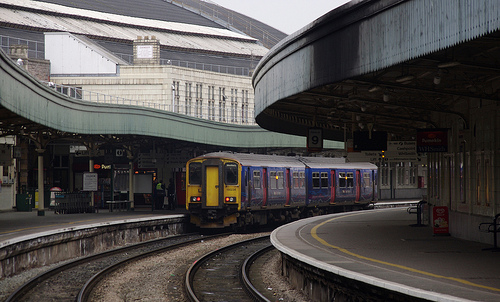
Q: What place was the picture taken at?
A: It was taken at the station.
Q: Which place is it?
A: It is a station.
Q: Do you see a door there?
A: Yes, there is a door.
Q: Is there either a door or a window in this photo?
A: Yes, there is a door.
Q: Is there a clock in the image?
A: No, there are no clocks.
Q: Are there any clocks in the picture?
A: No, there are no clocks.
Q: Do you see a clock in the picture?
A: No, there are no clocks.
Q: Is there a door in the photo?
A: Yes, there is a door.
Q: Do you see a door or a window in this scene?
A: Yes, there is a door.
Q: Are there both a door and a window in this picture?
A: Yes, there are both a door and a window.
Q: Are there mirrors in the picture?
A: No, there are no mirrors.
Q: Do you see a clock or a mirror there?
A: No, there are no mirrors or clocks.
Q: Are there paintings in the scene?
A: No, there are no paintings.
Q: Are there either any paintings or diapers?
A: No, there are no paintings or diapers.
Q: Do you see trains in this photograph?
A: Yes, there is a train.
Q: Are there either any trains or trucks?
A: Yes, there is a train.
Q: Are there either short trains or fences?
A: Yes, there is a short train.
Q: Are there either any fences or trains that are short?
A: Yes, the train is short.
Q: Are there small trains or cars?
A: Yes, there is a small train.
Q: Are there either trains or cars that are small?
A: Yes, the train is small.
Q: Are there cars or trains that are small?
A: Yes, the train is small.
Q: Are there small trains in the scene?
A: Yes, there is a small train.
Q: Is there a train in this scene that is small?
A: Yes, there is a train that is small.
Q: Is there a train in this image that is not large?
A: Yes, there is a small train.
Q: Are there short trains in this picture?
A: Yes, there is a short train.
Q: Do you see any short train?
A: Yes, there is a short train.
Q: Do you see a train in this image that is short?
A: Yes, there is a train that is short.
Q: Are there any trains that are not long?
A: Yes, there is a short train.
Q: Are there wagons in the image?
A: No, there are no wagons.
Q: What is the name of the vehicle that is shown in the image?
A: The vehicle is a train.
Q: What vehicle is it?
A: The vehicle is a train.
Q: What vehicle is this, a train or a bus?
A: That is a train.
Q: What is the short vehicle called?
A: The vehicle is a train.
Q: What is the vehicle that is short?
A: The vehicle is a train.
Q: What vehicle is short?
A: The vehicle is a train.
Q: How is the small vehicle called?
A: The vehicle is a train.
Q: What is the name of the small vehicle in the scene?
A: The vehicle is a train.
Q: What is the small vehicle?
A: The vehicle is a train.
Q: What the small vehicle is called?
A: The vehicle is a train.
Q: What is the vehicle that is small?
A: The vehicle is a train.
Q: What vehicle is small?
A: The vehicle is a train.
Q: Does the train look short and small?
A: Yes, the train is short and small.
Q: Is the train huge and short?
A: No, the train is short but small.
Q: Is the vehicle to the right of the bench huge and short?
A: No, the train is short but small.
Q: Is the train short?
A: Yes, the train is short.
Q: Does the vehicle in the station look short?
A: Yes, the train is short.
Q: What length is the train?
A: The train is short.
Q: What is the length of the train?
A: The train is short.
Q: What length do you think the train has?
A: The train has short length.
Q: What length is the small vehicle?
A: The train is short.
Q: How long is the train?
A: The train is short.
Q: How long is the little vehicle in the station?
A: The train is short.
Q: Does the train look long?
A: No, the train is short.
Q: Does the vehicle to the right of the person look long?
A: No, the train is short.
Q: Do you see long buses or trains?
A: No, there is a train but it is short.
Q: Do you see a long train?
A: No, there is a train but it is short.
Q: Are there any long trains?
A: No, there is a train but it is short.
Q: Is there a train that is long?
A: No, there is a train but it is short.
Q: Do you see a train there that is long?
A: No, there is a train but it is short.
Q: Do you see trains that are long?
A: No, there is a train but it is short.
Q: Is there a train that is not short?
A: No, there is a train but it is short.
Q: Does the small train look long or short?
A: The train is short.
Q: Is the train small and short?
A: Yes, the train is small and short.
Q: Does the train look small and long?
A: No, the train is small but short.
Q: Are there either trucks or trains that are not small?
A: No, there is a train but it is small.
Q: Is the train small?
A: Yes, the train is small.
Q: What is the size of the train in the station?
A: The train is small.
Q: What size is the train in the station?
A: The train is small.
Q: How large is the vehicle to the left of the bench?
A: The train is small.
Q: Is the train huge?
A: No, the train is small.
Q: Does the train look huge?
A: No, the train is small.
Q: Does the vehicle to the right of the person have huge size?
A: No, the train is small.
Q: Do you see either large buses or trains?
A: No, there is a train but it is small.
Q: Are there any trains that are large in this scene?
A: No, there is a train but it is small.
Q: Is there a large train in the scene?
A: No, there is a train but it is small.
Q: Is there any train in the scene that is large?
A: No, there is a train but it is small.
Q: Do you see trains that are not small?
A: No, there is a train but it is small.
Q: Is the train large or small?
A: The train is small.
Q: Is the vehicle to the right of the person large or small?
A: The train is small.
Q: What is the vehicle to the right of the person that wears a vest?
A: The vehicle is a train.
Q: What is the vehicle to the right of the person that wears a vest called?
A: The vehicle is a train.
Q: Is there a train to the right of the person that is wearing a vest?
A: Yes, there is a train to the right of the person.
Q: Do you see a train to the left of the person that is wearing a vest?
A: No, the train is to the right of the person.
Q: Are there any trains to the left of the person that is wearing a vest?
A: No, the train is to the right of the person.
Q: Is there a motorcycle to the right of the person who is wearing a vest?
A: No, there is a train to the right of the person.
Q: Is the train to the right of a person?
A: Yes, the train is to the right of a person.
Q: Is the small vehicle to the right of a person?
A: Yes, the train is to the right of a person.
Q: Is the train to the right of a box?
A: No, the train is to the right of a person.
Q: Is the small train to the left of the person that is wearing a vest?
A: No, the train is to the right of the person.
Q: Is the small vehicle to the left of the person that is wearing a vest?
A: No, the train is to the right of the person.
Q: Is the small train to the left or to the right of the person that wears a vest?
A: The train is to the right of the person.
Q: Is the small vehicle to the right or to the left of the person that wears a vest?
A: The train is to the right of the person.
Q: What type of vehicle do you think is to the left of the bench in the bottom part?
A: The vehicle is a train.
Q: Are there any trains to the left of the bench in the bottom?
A: Yes, there is a train to the left of the bench.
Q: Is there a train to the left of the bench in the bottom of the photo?
A: Yes, there is a train to the left of the bench.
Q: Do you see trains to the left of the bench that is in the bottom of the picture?
A: Yes, there is a train to the left of the bench.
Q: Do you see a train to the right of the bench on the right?
A: No, the train is to the left of the bench.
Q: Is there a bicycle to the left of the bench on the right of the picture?
A: No, there is a train to the left of the bench.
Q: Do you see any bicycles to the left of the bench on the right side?
A: No, there is a train to the left of the bench.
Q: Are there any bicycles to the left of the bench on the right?
A: No, there is a train to the left of the bench.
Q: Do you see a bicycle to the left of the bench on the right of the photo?
A: No, there is a train to the left of the bench.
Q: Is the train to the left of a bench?
A: Yes, the train is to the left of a bench.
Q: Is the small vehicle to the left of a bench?
A: Yes, the train is to the left of a bench.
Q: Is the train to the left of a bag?
A: No, the train is to the left of a bench.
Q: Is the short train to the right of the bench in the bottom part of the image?
A: No, the train is to the left of the bench.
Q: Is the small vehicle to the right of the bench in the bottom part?
A: No, the train is to the left of the bench.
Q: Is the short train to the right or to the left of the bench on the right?
A: The train is to the left of the bench.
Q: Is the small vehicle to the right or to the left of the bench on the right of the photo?
A: The train is to the left of the bench.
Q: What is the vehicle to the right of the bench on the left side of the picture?
A: The vehicle is a train.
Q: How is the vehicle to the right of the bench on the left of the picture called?
A: The vehicle is a train.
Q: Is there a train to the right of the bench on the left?
A: Yes, there is a train to the right of the bench.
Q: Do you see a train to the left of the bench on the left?
A: No, the train is to the right of the bench.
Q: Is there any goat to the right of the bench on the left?
A: No, there is a train to the right of the bench.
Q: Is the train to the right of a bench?
A: Yes, the train is to the right of a bench.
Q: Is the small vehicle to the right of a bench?
A: Yes, the train is to the right of a bench.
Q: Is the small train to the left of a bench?
A: No, the train is to the right of a bench.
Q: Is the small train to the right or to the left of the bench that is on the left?
A: The train is to the right of the bench.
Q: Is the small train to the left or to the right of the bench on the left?
A: The train is to the right of the bench.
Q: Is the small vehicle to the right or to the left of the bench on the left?
A: The train is to the right of the bench.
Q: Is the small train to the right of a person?
A: Yes, the train is to the right of a person.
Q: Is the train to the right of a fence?
A: No, the train is to the right of a person.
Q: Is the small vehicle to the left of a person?
A: No, the train is to the right of a person.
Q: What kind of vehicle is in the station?
A: The vehicle is a train.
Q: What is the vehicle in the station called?
A: The vehicle is a train.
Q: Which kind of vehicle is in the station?
A: The vehicle is a train.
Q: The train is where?
A: The train is in the station.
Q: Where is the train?
A: The train is in the station.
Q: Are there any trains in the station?
A: Yes, there is a train in the station.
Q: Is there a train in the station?
A: Yes, there is a train in the station.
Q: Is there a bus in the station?
A: No, there is a train in the station.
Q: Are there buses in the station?
A: No, there is a train in the station.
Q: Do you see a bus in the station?
A: No, there is a train in the station.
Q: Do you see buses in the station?
A: No, there is a train in the station.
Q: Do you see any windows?
A: Yes, there is a window.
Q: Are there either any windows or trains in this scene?
A: Yes, there is a window.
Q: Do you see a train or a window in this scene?
A: Yes, there is a window.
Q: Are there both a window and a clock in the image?
A: No, there is a window but no clocks.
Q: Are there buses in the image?
A: No, there are no buses.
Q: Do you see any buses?
A: No, there are no buses.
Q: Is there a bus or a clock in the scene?
A: No, there are no buses or clocks.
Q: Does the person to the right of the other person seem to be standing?
A: Yes, the person is standing.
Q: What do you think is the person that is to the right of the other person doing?
A: The person is standing.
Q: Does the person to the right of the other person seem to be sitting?
A: No, the person is standing.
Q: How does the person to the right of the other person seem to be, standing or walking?
A: The person is standing.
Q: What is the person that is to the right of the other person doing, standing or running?
A: The person is standing.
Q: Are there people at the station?
A: Yes, there is a person at the station.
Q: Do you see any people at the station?
A: Yes, there is a person at the station.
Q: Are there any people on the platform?
A: Yes, there is a person on the platform.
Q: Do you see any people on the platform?
A: Yes, there is a person on the platform.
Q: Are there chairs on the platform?
A: No, there is a person on the platform.